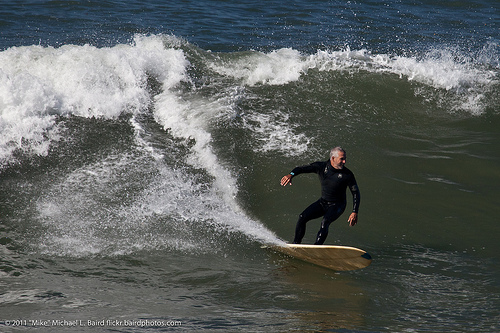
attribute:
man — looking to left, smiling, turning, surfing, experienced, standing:
[277, 142, 368, 249]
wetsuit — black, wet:
[289, 159, 368, 246]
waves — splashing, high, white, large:
[4, 30, 500, 210]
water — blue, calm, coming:
[2, 2, 500, 61]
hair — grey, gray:
[329, 143, 345, 153]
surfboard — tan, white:
[272, 239, 376, 280]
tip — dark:
[360, 249, 373, 262]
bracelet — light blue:
[288, 170, 295, 178]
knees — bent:
[296, 210, 307, 221]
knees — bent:
[319, 219, 329, 229]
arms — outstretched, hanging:
[345, 176, 360, 226]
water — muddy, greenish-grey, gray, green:
[1, 205, 500, 332]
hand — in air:
[278, 172, 293, 187]